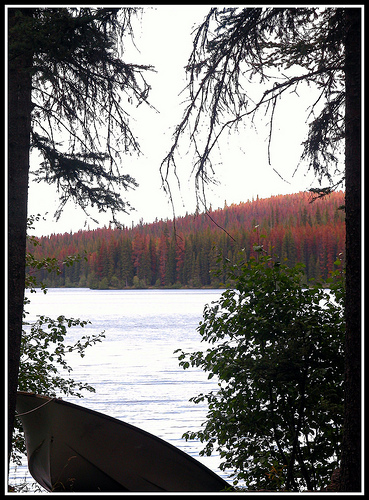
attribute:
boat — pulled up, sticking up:
[13, 382, 243, 490]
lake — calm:
[25, 283, 352, 481]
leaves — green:
[15, 17, 72, 51]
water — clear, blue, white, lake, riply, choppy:
[97, 385, 197, 421]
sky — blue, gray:
[38, 5, 338, 202]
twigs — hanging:
[252, 88, 304, 111]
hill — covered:
[30, 189, 346, 287]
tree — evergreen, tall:
[291, 11, 358, 498]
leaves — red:
[158, 243, 164, 248]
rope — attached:
[25, 392, 59, 419]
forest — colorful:
[28, 195, 343, 286]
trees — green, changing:
[77, 232, 326, 271]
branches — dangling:
[166, 7, 351, 195]